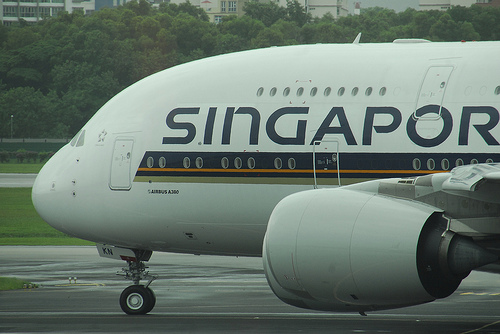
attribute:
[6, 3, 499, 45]
trees — distant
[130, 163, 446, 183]
lines — yellow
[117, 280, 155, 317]
wheels — Round 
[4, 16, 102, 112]
trees — distant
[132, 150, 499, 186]
stripe — blue orange & gold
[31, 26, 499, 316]
plane — ventilated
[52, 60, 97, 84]
leaves — green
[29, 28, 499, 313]
airplane — large, big, white